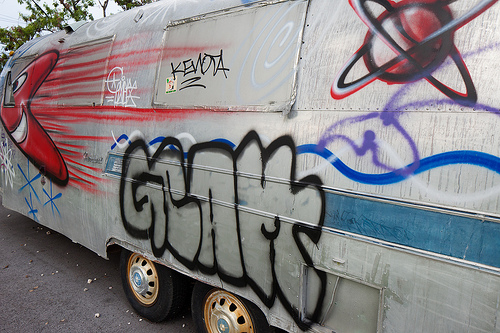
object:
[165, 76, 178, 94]
sticker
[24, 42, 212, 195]
red paint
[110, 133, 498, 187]
blue paint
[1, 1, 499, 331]
van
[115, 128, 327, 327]
graffiti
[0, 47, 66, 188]
design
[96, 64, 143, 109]
letters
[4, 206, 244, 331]
parking lot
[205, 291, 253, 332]
hubcap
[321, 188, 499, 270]
stripe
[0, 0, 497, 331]
bus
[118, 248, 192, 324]
tires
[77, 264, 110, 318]
rocks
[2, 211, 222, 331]
road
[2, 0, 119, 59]
sky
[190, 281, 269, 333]
tire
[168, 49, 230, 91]
graffiti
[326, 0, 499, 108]
graffiti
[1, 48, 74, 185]
graffiti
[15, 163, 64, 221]
star graffiti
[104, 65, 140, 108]
white handwriting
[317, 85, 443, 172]
purple writing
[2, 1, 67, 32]
green tree